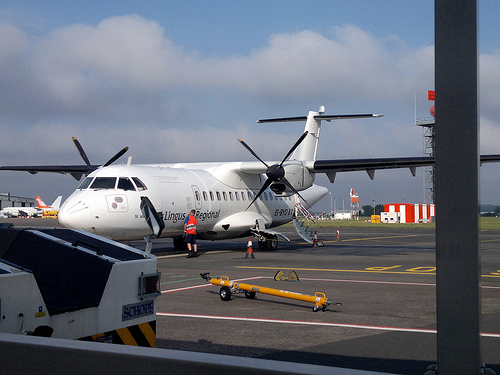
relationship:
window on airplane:
[77, 176, 145, 190] [2, 104, 483, 252]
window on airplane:
[77, 176, 91, 189] [2, 104, 483, 252]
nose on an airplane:
[50, 198, 91, 261] [2, 104, 483, 252]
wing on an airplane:
[302, 157, 498, 180] [57, 109, 495, 240]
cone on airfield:
[243, 234, 255, 260] [306, 190, 471, 258]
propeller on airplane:
[237, 131, 309, 211] [5, 107, 450, 257]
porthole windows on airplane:
[195, 190, 292, 201] [2, 104, 483, 252]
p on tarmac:
[364, 260, 400, 274] [332, 246, 452, 335]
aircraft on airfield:
[0, 103, 386, 251] [0, 190, 499, 375]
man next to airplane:
[181, 208, 201, 258] [2, 104, 483, 252]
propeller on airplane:
[237, 131, 313, 214] [2, 104, 483, 252]